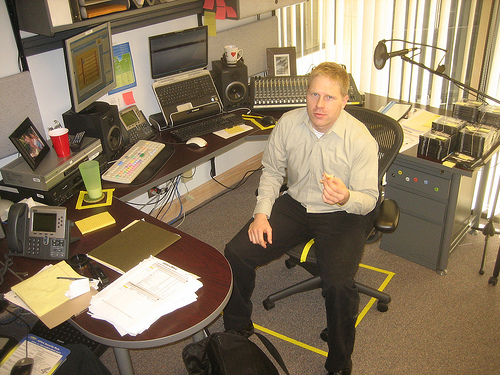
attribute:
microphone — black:
[373, 37, 419, 69]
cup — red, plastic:
[49, 128, 72, 160]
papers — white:
[88, 255, 204, 338]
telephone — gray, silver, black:
[5, 204, 81, 262]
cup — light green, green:
[77, 161, 104, 200]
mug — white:
[223, 46, 244, 68]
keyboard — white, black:
[101, 138, 166, 183]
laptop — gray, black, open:
[147, 26, 225, 128]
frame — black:
[9, 117, 52, 172]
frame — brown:
[267, 47, 297, 79]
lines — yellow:
[252, 262, 395, 360]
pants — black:
[224, 192, 378, 373]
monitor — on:
[62, 21, 118, 114]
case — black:
[182, 323, 292, 374]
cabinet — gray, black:
[379, 146, 485, 276]